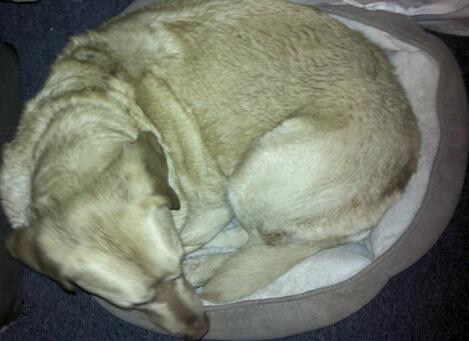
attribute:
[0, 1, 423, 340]
dog — sleeping, tan, short haired, curled up, light tan, large, curled, laying down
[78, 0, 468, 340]
bed — tan, white, plush, grey, round, cushioned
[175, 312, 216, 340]
nose — brown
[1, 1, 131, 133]
carpet — dark blue, blue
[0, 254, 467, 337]
carpet — dark blue, blue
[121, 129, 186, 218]
ear — folded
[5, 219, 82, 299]
ear — folded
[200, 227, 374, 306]
tail — off-white, tucked under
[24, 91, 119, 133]
nape — hairy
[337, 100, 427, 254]
butt — hairy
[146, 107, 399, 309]
legs — folded